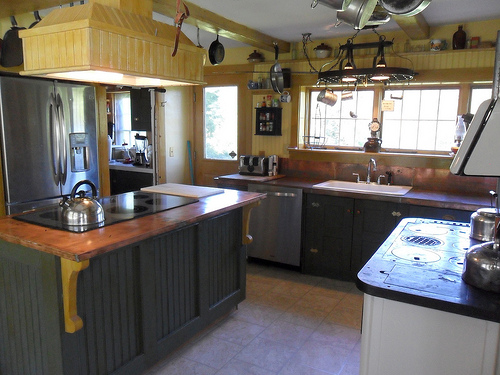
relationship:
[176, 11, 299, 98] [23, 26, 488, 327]
pans in kitchen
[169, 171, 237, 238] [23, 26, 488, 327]
island in kitchen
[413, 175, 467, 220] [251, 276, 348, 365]
counter above floor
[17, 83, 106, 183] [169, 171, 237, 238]
fridge near island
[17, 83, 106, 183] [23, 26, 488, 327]
fridge in kitchen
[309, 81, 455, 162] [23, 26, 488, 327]
window in kitchen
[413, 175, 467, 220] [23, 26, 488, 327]
counter in kitchen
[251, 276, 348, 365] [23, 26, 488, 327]
floor in kitchen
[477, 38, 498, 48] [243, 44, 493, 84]
item on shelf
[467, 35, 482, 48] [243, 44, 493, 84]
item on shelf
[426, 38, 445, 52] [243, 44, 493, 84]
item on shelf